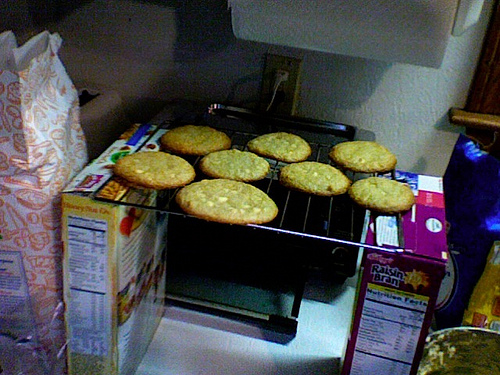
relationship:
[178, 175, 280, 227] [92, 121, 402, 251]
cookie atop rack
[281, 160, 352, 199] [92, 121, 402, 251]
cookie atop rack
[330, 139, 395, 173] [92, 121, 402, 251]
cookie atop rack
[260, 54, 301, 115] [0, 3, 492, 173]
plug in wall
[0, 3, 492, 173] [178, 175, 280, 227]
wall behind cookie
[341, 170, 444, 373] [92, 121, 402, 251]
box holding up rack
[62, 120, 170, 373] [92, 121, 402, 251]
box holding up rack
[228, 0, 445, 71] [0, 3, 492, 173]
towels are on wall